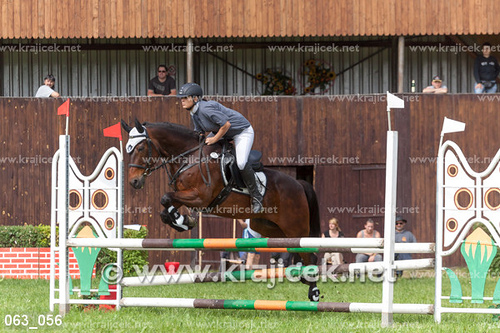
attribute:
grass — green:
[161, 285, 387, 324]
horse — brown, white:
[114, 116, 324, 323]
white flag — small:
[382, 88, 407, 130]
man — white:
[146, 55, 176, 97]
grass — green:
[337, 273, 366, 308]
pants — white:
[227, 124, 259, 166]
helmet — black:
[169, 82, 204, 100]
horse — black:
[122, 115, 324, 295]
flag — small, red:
[50, 95, 73, 121]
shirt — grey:
[191, 96, 244, 136]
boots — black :
[229, 165, 284, 222]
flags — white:
[368, 92, 478, 150]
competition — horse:
[32, 60, 409, 331]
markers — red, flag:
[50, 99, 124, 148]